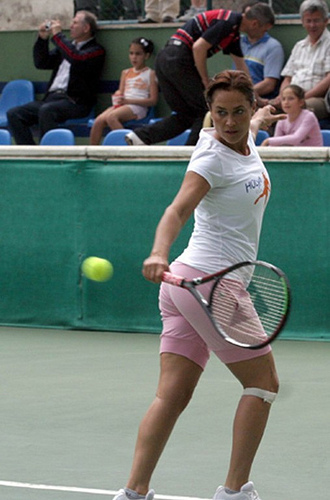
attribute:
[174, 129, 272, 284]
t-shirt — white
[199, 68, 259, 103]
hair — brown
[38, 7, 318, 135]
people — sitting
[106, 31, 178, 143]
girl — young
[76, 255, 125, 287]
tennis ball — green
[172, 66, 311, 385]
woman — hitting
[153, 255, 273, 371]
pink shorts — pair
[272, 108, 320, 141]
shirt — pink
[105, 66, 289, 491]
tennis player — female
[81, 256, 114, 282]
tennis ball — yellow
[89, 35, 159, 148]
girl — sitting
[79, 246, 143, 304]
ball — green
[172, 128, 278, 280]
t-shirt — white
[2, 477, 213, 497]
white line — painted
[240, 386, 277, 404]
band — white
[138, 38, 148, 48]
hair bow — white